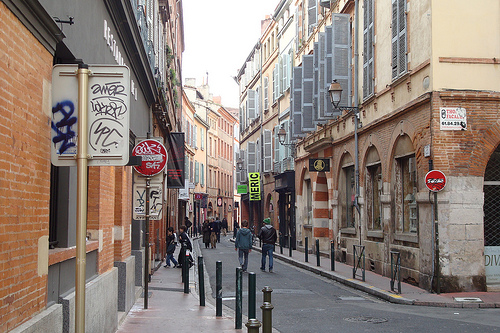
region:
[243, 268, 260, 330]
Green post in the pavement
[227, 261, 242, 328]
Green post in the pavement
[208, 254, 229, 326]
Green post in the pavement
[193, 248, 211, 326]
Green post in the pavement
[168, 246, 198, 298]
Green post in the pavement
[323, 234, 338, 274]
Green post in the pavement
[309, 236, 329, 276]
Green post in the pavement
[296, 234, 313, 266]
Green post in the pavement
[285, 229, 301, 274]
Green post in the pavement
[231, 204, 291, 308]
Two males on the pavement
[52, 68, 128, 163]
Graffiti on a sign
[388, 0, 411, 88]
Window on a building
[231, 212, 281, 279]
Two people walking on the road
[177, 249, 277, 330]
Many poles on the sidewalk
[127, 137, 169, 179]
A round and red sign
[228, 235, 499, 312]
Curb of the sidewalk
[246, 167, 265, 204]
Black writing on yellow sign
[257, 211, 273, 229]
Green hat on person's head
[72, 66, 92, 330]
A pole holding up a sign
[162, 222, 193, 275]
People standing on the sidewalk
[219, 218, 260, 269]
a key on the keyboard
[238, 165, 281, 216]
this is a sign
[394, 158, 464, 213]
this is a sign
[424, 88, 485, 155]
this is a sign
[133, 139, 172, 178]
this is a sign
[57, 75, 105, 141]
graffiti on sign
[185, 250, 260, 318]
black metal posts line sidewalk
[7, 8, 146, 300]
buildings made of brick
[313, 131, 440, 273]
arched windows in this building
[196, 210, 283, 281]
people walking down ally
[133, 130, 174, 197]
red round caution sign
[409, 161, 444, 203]
round red caution sign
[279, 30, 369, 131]
windows are open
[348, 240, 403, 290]
two metal gates line the sidewalk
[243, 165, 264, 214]
yellow banner says meric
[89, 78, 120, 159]
grafitti is on the sign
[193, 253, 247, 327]
the poles are green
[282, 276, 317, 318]
the road is black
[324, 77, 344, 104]
the light is off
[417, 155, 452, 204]
the sign is round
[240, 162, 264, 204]
the banner is yellow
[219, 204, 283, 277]
the men are standing in the street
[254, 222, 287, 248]
the jacket is black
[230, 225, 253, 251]
the jacket is blue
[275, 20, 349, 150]
the shutters are open